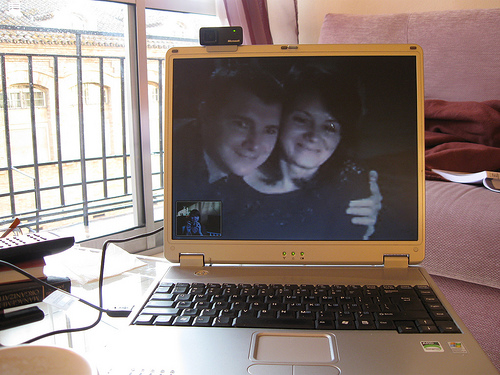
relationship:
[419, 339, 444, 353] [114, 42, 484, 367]
stickers on laptop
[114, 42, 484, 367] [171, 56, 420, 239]
laptop with screensaver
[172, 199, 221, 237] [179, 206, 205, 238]
photo of girl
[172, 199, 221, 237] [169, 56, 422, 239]
photo on screen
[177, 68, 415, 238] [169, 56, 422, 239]
couple on screen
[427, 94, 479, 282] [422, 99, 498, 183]
area with blanket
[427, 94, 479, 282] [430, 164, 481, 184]
area with book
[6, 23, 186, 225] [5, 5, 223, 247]
fencing outside window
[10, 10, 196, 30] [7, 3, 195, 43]
tiling on roof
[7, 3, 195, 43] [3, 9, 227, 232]
roof outside window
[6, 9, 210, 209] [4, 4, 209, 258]
building outside window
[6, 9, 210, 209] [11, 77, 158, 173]
building with windows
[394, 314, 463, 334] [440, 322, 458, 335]
set of key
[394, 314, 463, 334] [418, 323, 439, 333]
set of key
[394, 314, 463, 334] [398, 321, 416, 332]
set of key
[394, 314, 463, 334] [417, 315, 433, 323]
set of key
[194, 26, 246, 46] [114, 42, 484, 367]
webcam on laptop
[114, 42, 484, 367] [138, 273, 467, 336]
laptop has keyboard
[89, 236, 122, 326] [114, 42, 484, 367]
cable near laptop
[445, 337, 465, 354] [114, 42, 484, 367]
sticker on laptop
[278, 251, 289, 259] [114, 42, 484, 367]
light on laptop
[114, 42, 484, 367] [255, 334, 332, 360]
laptop has pad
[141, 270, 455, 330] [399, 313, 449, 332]
keyboard has keys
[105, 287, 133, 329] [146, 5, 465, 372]
drive on laptop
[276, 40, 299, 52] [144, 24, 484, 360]
logo on laptop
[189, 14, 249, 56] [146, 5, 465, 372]
webcam on laptop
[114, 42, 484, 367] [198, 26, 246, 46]
laptop with webcam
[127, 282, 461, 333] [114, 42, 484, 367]
keyboard on a laptop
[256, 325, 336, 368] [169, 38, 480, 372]
pad on a laptop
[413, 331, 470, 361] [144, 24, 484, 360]
stickers on a laptop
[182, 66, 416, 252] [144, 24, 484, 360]
screen on a laptop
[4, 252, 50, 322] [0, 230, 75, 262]
books under remote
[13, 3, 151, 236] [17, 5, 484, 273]
windows in a room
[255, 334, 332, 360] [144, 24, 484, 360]
pad on laptop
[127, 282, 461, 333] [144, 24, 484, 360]
keyboard on laptop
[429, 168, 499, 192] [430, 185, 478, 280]
book on bed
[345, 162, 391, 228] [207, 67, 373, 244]
hand on people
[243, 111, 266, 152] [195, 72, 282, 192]
nose of a man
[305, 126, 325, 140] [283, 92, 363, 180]
nose of a woman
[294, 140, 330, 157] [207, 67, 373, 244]
mouth of a people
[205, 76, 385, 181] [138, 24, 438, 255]
people on monitor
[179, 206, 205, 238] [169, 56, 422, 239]
girl on screen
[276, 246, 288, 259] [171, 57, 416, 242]
light on screen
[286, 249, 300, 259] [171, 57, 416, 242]
light on screen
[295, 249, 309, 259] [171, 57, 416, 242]
light on screen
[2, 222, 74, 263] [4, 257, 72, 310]
remote on books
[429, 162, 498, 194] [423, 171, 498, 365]
book on sofa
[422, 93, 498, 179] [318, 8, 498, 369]
blanket on sofa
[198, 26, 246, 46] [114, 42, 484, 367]
webcam mounted on laptop